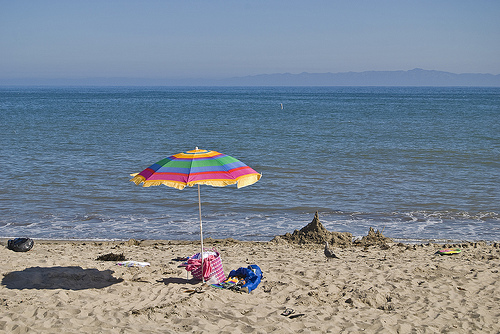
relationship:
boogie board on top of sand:
[437, 247, 460, 255] [0, 238, 500, 333]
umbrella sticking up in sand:
[128, 146, 263, 290] [0, 238, 500, 333]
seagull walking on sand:
[114, 260, 152, 281] [0, 238, 500, 333]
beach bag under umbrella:
[185, 250, 232, 285] [128, 146, 263, 290]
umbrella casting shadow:
[128, 146, 263, 290] [2, 266, 125, 292]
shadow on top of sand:
[2, 266, 125, 292] [0, 238, 500, 333]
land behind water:
[0, 69, 500, 90] [0, 86, 500, 241]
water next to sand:
[0, 86, 500, 241] [0, 238, 500, 333]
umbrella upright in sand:
[128, 146, 263, 290] [0, 238, 500, 333]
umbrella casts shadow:
[128, 146, 263, 290] [2, 266, 125, 292]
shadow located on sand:
[2, 266, 125, 292] [0, 238, 500, 333]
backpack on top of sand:
[212, 265, 263, 292] [0, 238, 500, 333]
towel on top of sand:
[212, 278, 249, 295] [0, 238, 500, 333]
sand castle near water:
[272, 211, 403, 249] [0, 86, 500, 241]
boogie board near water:
[437, 247, 460, 255] [0, 86, 500, 241]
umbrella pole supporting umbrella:
[196, 184, 205, 254] [128, 146, 263, 290]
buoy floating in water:
[278, 101, 284, 111] [0, 86, 500, 241]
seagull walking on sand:
[323, 241, 343, 263] [0, 238, 500, 333]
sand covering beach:
[0, 238, 500, 333] [0, 236, 500, 332]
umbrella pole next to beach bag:
[196, 184, 205, 254] [185, 250, 232, 285]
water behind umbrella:
[0, 86, 500, 241] [128, 146, 263, 290]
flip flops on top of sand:
[280, 307, 306, 318] [0, 238, 500, 333]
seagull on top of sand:
[323, 241, 343, 263] [0, 238, 500, 333]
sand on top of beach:
[0, 238, 500, 333] [0, 236, 500, 332]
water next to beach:
[0, 86, 500, 241] [0, 236, 500, 332]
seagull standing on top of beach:
[323, 241, 343, 263] [0, 236, 500, 332]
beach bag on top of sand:
[185, 250, 232, 285] [0, 238, 500, 333]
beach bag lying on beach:
[185, 250, 232, 285] [0, 236, 500, 332]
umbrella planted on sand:
[128, 146, 263, 290] [0, 238, 500, 333]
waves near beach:
[0, 208, 499, 239] [0, 236, 500, 332]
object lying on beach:
[6, 238, 34, 252] [0, 236, 500, 332]